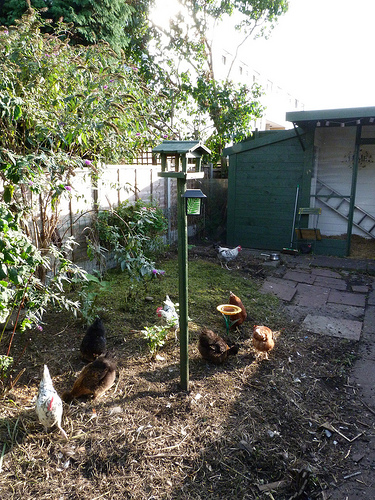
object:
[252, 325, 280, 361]
chicken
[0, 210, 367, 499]
yard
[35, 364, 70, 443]
chicken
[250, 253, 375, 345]
sidewalk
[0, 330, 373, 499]
mulch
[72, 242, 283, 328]
grass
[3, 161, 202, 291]
fence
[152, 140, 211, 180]
feeder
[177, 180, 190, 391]
pole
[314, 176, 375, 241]
ladder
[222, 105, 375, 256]
building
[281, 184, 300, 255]
broom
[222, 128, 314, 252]
chicken coop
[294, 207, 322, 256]
chair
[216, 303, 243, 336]
pot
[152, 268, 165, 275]
flowers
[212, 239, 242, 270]
chicken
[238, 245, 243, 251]
head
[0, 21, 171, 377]
tree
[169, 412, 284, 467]
straw